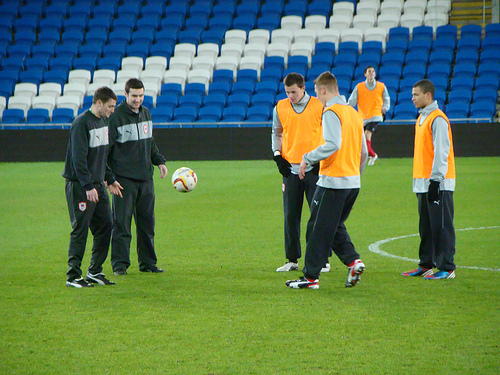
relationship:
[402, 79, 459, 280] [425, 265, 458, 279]
man has shoe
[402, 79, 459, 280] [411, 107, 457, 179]
man has vest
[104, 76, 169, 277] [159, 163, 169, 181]
man has hand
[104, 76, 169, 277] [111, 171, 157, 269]
man wearing pants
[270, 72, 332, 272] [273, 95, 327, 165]
man wearing vest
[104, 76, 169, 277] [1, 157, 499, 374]
man on field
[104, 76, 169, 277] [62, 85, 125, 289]
man by man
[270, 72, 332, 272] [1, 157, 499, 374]
man on field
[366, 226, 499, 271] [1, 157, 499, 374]
line on field